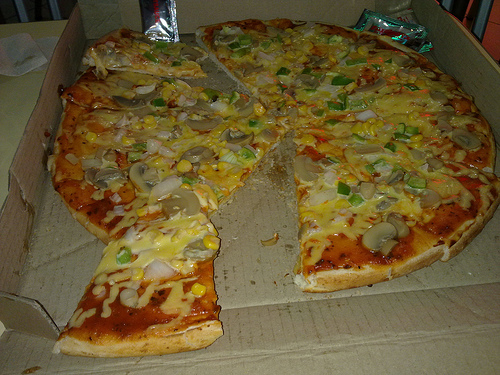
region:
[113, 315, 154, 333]
Red sauce on pizza.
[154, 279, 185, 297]
Cheese melted on pizza.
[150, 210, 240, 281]
Pizza cut into slices.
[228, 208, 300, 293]
Pizza sitting on card board box.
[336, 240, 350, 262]
Red sauce on pizza.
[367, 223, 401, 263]
Piece of mushroom on pizza.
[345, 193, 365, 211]
Piece of green pepper on pizza.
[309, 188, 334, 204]
White onion on top of pizza.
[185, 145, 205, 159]
Piece of mushroom on pizza.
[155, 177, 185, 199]
White onion on top of pizza.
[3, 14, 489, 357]
pizza slices in a box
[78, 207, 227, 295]
cheese on a pizza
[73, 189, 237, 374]
pizza slice with toppings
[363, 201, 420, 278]
mashrooms on a pizza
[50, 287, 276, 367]
pizza crust on a box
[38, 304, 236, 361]
pizza crust with red sauce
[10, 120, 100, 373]
section of a piza box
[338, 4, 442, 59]
sauce packets next to pizza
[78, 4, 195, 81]
a silver packet of sauce near a slice of pizza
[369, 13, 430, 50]
silver packets in the box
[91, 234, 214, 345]
slice of pizza on the outside part of the box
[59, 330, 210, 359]
think crust of the pizza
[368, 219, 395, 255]
mushroom on the pizza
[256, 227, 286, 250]
cheese on the box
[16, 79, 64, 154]
box is on the table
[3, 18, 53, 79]
napkins on the table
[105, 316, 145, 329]
pizza sauce on the pizza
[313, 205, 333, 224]
melted cheese on the pizza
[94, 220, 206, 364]
slice of pizza in box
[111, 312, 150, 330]
sauce on pizza slice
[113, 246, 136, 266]
green pepper on pizza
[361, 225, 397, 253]
mushroom on top pizza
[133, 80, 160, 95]
onions on top of pizza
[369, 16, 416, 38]
green foil in box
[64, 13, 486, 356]
this is a pizza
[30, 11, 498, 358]
a pizza in a cardboard box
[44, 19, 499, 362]
this is a large pizza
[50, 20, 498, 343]
the pizza is on cardboard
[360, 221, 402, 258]
this is a mushroom slice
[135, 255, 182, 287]
this is chopped white onion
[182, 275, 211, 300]
this is a single kernel of corn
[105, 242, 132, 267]
this is a piece of chopped bell pepper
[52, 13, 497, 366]
the pizza has many toppings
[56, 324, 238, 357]
this is the crust